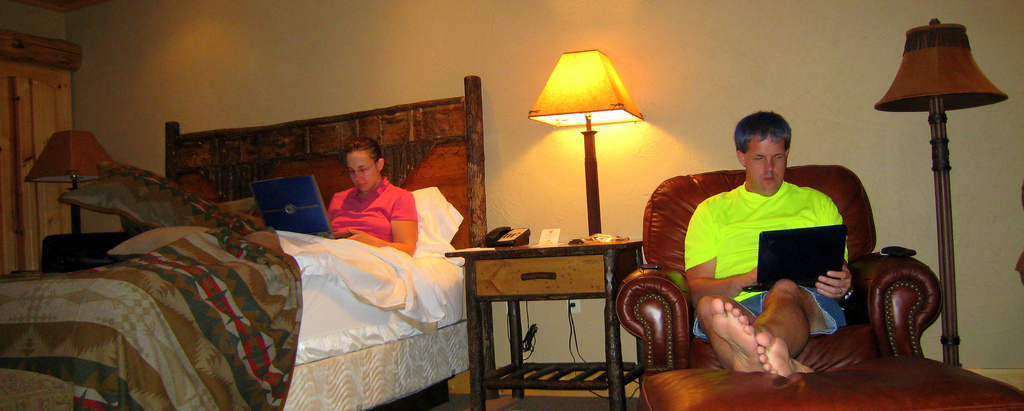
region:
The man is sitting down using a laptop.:
[770, 147, 925, 258]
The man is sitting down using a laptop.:
[596, 235, 805, 357]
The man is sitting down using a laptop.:
[552, 193, 819, 324]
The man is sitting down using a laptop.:
[429, 168, 663, 336]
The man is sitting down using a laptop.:
[400, 124, 679, 271]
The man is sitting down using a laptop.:
[514, 104, 827, 298]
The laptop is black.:
[742, 225, 861, 296]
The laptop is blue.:
[249, 173, 336, 237]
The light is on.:
[521, 50, 654, 246]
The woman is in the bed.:
[322, 138, 425, 269]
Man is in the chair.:
[682, 98, 861, 378]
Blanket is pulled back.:
[214, 205, 412, 380]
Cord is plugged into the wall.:
[553, 291, 595, 326]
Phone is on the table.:
[471, 218, 541, 251]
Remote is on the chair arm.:
[879, 233, 921, 266]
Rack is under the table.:
[493, 350, 640, 392]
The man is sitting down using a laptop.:
[640, 215, 780, 349]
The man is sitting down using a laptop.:
[429, 158, 584, 257]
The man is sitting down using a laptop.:
[729, 131, 827, 217]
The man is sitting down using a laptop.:
[479, 294, 496, 317]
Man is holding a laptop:
[740, 200, 862, 290]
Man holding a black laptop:
[744, 215, 858, 296]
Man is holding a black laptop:
[737, 216, 858, 299]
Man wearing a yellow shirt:
[672, 172, 873, 302]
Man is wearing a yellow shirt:
[653, 174, 875, 311]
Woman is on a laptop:
[242, 160, 389, 246]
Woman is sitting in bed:
[244, 117, 419, 270]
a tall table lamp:
[531, 40, 658, 234]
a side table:
[447, 241, 641, 407]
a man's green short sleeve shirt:
[681, 186, 843, 288]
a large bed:
[0, 79, 535, 406]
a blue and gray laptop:
[250, 167, 346, 248]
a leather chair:
[620, 157, 944, 382]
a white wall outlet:
[557, 297, 590, 310]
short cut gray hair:
[734, 108, 789, 148]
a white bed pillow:
[408, 184, 462, 249]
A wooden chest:
[2, 13, 121, 274]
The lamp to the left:
[18, 118, 158, 273]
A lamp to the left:
[15, 118, 132, 245]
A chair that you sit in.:
[610, 157, 923, 372]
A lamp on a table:
[528, 45, 643, 242]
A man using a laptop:
[683, 108, 858, 374]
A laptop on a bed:
[255, 164, 347, 235]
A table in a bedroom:
[443, 234, 650, 397]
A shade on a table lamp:
[525, 48, 640, 129]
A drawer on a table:
[467, 247, 607, 299]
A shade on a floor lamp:
[875, 21, 1005, 119]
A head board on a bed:
[158, 73, 484, 254]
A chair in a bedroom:
[619, 161, 942, 362]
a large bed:
[30, 115, 486, 404]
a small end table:
[452, 244, 623, 399]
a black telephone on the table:
[484, 219, 526, 243]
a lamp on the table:
[525, 48, 633, 232]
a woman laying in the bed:
[256, 133, 421, 251]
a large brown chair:
[636, 157, 1001, 393]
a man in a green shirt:
[642, 117, 955, 403]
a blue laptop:
[258, 171, 332, 228]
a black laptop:
[754, 229, 847, 281]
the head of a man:
[722, 98, 803, 191]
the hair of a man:
[713, 95, 812, 153]